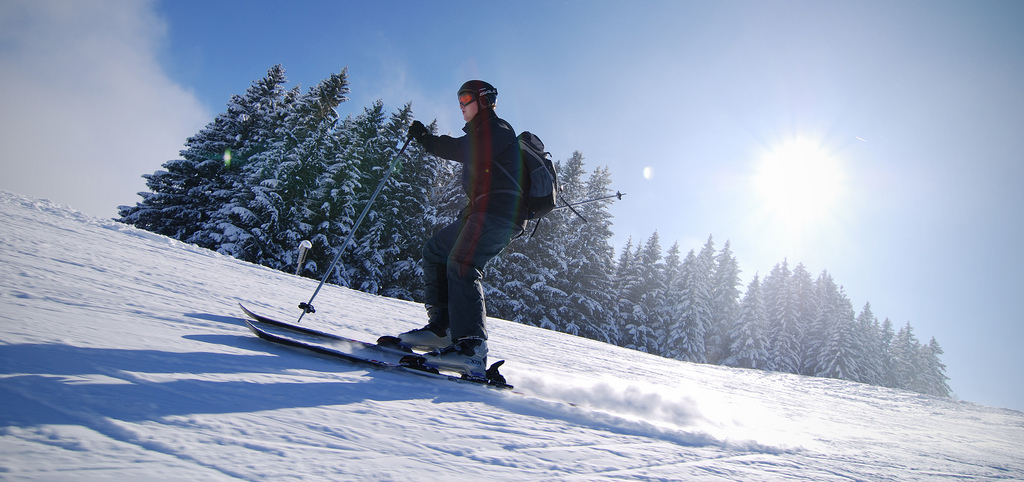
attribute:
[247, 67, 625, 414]
man — tall, skiing, white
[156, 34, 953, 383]
trees — green, white, dark, tall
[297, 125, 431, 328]
poles — blue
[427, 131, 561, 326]
gear — dark, black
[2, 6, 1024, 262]
sky — big, bright, clear, blue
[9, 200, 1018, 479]
snow — tall, fluffy, white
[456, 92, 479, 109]
goggles — orange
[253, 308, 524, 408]
skis — black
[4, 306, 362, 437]
shadow — black